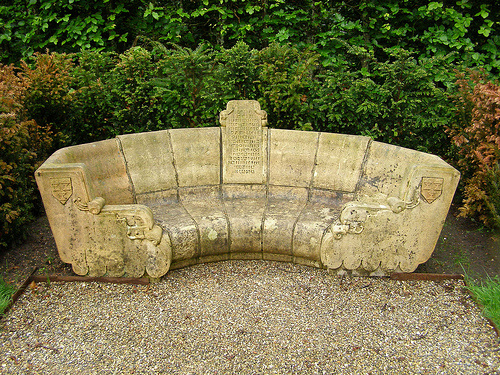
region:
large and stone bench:
[45, 129, 454, 296]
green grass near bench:
[476, 280, 498, 312]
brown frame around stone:
[16, 264, 454, 298]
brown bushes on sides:
[445, 64, 489, 234]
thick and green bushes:
[0, 9, 485, 74]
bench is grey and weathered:
[53, 151, 390, 270]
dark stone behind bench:
[31, 212, 51, 274]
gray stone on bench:
[123, 139, 172, 187]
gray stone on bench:
[176, 129, 221, 179]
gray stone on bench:
[191, 196, 216, 244]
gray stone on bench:
[234, 124, 276, 173]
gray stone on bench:
[234, 194, 264, 261]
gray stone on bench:
[268, 132, 313, 179]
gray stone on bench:
[273, 197, 295, 246]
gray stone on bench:
[323, 130, 360, 206]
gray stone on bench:
[376, 150, 418, 206]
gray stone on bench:
[291, 209, 323, 253]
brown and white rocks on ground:
[266, 315, 313, 344]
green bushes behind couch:
[342, 95, 384, 114]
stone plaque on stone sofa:
[48, 180, 80, 218]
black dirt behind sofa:
[458, 235, 485, 282]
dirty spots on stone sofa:
[163, 196, 353, 246]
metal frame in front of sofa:
[30, 253, 70, 295]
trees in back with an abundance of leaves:
[44, 18, 104, 48]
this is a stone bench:
[22, 90, 476, 295]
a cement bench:
[18, 93, 498, 322]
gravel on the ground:
[20, 283, 495, 372]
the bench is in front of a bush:
[16, 10, 495, 297]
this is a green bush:
[4, 0, 497, 45]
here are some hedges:
[5, 37, 499, 127]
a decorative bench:
[0, 105, 485, 312]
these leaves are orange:
[460, 64, 497, 234]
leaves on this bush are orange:
[4, 48, 61, 247]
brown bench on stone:
[68, 114, 420, 260]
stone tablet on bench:
[197, 102, 297, 207]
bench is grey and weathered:
[147, 166, 374, 239]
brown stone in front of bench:
[124, 282, 330, 367]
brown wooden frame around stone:
[5, 257, 448, 310]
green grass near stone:
[475, 279, 499, 322]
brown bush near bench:
[455, 74, 499, 182]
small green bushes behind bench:
[30, 60, 447, 152]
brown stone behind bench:
[4, 221, 60, 286]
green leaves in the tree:
[350, 84, 378, 104]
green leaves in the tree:
[399, 101, 429, 123]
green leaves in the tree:
[412, 104, 459, 129]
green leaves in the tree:
[333, 89, 366, 119]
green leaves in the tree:
[293, 86, 328, 119]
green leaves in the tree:
[170, 89, 206, 117]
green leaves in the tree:
[428, 18, 468, 50]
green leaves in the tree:
[260, 11, 306, 38]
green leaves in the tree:
[197, 3, 248, 48]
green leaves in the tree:
[115, 6, 175, 39]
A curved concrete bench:
[32, 97, 462, 284]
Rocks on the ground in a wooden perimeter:
[0, 256, 498, 373]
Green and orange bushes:
[0, 36, 498, 253]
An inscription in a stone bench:
[215, 97, 270, 184]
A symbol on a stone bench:
[45, 174, 74, 207]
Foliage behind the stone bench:
[0, 0, 499, 255]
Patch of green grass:
[455, 256, 499, 336]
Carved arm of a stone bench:
[32, 162, 170, 279]